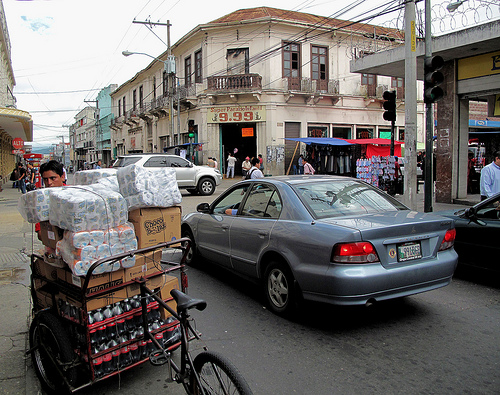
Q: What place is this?
A: It is a city.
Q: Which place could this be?
A: It is a city.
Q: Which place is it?
A: It is a city.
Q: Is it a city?
A: Yes, it is a city.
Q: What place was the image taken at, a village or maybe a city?
A: It was taken at a city.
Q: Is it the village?
A: No, it is the city.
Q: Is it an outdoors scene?
A: Yes, it is outdoors.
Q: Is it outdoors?
A: Yes, it is outdoors.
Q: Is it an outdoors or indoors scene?
A: It is outdoors.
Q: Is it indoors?
A: No, it is outdoors.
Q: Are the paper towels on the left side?
A: Yes, the paper towels are on the left of the image.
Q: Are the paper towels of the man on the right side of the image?
A: No, the paper towels are on the left of the image.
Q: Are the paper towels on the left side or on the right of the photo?
A: The paper towels are on the left of the image.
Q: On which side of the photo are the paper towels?
A: The paper towels are on the left of the image.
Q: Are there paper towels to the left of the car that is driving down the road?
A: Yes, there are paper towels to the left of the car.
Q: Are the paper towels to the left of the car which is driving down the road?
A: Yes, the paper towels are to the left of the car.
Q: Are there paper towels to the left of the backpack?
A: Yes, there are paper towels to the left of the backpack.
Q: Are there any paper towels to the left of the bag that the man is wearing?
A: Yes, there are paper towels to the left of the backpack.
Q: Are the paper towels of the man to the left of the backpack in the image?
A: Yes, the paper towels are to the left of the backpack.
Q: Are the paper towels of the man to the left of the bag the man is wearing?
A: Yes, the paper towels are to the left of the backpack.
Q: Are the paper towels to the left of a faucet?
A: No, the paper towels are to the left of the backpack.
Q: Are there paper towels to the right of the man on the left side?
A: Yes, there are paper towels to the right of the man.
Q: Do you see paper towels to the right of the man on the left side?
A: Yes, there are paper towels to the right of the man.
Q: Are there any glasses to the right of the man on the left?
A: No, there are paper towels to the right of the man.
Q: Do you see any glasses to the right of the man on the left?
A: No, there are paper towels to the right of the man.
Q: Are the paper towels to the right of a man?
A: Yes, the paper towels are to the right of a man.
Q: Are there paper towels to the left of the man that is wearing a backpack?
A: Yes, there are paper towels to the left of the man.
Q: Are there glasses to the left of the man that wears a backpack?
A: No, there are paper towels to the left of the man.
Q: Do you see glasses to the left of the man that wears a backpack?
A: No, there are paper towels to the left of the man.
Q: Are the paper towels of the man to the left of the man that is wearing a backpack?
A: Yes, the paper towels are to the left of the man.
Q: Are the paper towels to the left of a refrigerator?
A: No, the paper towels are to the left of the man.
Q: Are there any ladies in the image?
A: No, there are no ladies.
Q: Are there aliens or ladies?
A: No, there are no ladies or aliens.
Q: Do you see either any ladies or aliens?
A: No, there are no ladies or aliens.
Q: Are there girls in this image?
A: No, there are no girls.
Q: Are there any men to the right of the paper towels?
A: Yes, there is a man to the right of the paper towels.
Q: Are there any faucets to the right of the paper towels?
A: No, there is a man to the right of the paper towels.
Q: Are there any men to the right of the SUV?
A: Yes, there is a man to the right of the SUV.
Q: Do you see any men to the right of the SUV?
A: Yes, there is a man to the right of the SUV.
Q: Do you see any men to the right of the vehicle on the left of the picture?
A: Yes, there is a man to the right of the SUV.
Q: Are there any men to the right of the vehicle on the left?
A: Yes, there is a man to the right of the SUV.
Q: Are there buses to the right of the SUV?
A: No, there is a man to the right of the SUV.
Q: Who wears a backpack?
A: The man wears a backpack.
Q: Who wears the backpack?
A: The man wears a backpack.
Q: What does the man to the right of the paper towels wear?
A: The man wears a backpack.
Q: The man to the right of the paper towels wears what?
A: The man wears a backpack.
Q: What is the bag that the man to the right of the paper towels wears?
A: The bag is a backpack.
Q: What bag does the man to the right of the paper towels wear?
A: The man wears a backpack.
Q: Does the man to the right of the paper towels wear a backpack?
A: Yes, the man wears a backpack.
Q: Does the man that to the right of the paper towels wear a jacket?
A: No, the man wears a backpack.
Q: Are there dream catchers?
A: No, there are no dream catchers.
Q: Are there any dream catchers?
A: No, there are no dream catchers.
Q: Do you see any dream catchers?
A: No, there are no dream catchers.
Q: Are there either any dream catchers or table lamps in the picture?
A: No, there are no dream catchers or table lamps.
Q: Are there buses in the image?
A: No, there are no buses.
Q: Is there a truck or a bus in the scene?
A: No, there are no buses or trucks.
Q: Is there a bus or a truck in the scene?
A: No, there are no buses or trucks.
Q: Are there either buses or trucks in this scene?
A: No, there are no buses or trucks.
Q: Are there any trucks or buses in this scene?
A: No, there are no buses or trucks.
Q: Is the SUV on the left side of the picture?
A: Yes, the SUV is on the left of the image.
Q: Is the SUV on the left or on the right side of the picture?
A: The SUV is on the left of the image.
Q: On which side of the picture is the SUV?
A: The SUV is on the left of the image.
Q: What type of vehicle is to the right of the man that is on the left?
A: The vehicle is a SUV.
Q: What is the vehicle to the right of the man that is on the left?
A: The vehicle is a SUV.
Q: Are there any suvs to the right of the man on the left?
A: Yes, there is a SUV to the right of the man.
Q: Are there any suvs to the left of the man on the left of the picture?
A: No, the SUV is to the right of the man.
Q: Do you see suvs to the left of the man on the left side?
A: No, the SUV is to the right of the man.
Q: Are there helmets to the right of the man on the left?
A: No, there is a SUV to the right of the man.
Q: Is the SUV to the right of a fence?
A: No, the SUV is to the right of a man.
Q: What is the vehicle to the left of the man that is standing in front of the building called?
A: The vehicle is a SUV.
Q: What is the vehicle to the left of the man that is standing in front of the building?
A: The vehicle is a SUV.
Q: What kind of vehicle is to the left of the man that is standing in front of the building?
A: The vehicle is a SUV.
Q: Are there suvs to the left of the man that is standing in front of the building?
A: Yes, there is a SUV to the left of the man.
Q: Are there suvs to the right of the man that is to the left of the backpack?
A: No, the SUV is to the left of the man.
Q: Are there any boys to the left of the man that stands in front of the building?
A: No, there is a SUV to the left of the man.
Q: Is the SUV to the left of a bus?
A: No, the SUV is to the left of the man.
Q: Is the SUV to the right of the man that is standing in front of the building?
A: No, the SUV is to the left of the man.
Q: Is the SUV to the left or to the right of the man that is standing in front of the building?
A: The SUV is to the left of the man.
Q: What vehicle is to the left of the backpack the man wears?
A: The vehicle is a SUV.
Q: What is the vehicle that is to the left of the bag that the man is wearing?
A: The vehicle is a SUV.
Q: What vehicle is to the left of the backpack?
A: The vehicle is a SUV.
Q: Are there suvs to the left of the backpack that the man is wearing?
A: Yes, there is a SUV to the left of the backpack.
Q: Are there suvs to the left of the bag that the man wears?
A: Yes, there is a SUV to the left of the backpack.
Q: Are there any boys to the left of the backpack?
A: No, there is a SUV to the left of the backpack.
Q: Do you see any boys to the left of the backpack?
A: No, there is a SUV to the left of the backpack.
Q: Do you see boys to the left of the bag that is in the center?
A: No, there is a SUV to the left of the backpack.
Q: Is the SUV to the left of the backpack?
A: Yes, the SUV is to the left of the backpack.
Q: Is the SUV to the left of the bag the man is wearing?
A: Yes, the SUV is to the left of the backpack.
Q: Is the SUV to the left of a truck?
A: No, the SUV is to the left of the backpack.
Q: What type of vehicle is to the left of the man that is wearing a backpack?
A: The vehicle is a SUV.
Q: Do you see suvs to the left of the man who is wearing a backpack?
A: Yes, there is a SUV to the left of the man.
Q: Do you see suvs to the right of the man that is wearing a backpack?
A: No, the SUV is to the left of the man.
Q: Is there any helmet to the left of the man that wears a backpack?
A: No, there is a SUV to the left of the man.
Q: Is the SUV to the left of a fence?
A: No, the SUV is to the left of the man.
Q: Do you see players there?
A: No, there are no players.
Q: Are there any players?
A: No, there are no players.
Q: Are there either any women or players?
A: No, there are no players or women.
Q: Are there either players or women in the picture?
A: No, there are no players or women.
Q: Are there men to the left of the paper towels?
A: Yes, there is a man to the left of the paper towels.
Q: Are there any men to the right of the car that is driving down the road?
A: No, the man is to the left of the car.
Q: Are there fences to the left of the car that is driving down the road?
A: No, there is a man to the left of the car.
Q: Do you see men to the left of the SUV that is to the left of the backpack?
A: Yes, there is a man to the left of the SUV.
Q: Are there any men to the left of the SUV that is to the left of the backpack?
A: Yes, there is a man to the left of the SUV.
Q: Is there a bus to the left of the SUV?
A: No, there is a man to the left of the SUV.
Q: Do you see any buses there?
A: No, there are no buses.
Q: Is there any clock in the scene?
A: No, there are no clocks.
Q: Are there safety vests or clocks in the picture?
A: No, there are no clocks or safety vests.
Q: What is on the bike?
A: The seat is on the bike.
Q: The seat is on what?
A: The seat is on the bike.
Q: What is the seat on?
A: The seat is on the bike.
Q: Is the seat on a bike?
A: Yes, the seat is on a bike.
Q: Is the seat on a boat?
A: No, the seat is on a bike.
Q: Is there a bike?
A: Yes, there is a bike.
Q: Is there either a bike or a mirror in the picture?
A: Yes, there is a bike.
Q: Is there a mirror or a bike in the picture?
A: Yes, there is a bike.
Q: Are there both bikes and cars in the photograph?
A: Yes, there are both a bike and a car.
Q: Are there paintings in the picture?
A: No, there are no paintings.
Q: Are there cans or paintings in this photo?
A: No, there are no paintings or cans.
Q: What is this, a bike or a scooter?
A: This is a bike.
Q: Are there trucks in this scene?
A: No, there are no trucks.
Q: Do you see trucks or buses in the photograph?
A: No, there are no trucks or buses.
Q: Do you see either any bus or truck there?
A: No, there are no trucks or buses.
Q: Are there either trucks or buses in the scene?
A: No, there are no trucks or buses.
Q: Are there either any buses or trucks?
A: No, there are no trucks or buses.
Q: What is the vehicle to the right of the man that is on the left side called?
A: The vehicle is a car.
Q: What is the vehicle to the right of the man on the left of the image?
A: The vehicle is a car.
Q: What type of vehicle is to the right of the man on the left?
A: The vehicle is a car.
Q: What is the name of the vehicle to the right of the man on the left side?
A: The vehicle is a car.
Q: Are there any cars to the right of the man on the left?
A: Yes, there is a car to the right of the man.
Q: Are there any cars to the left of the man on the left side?
A: No, the car is to the right of the man.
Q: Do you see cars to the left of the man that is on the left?
A: No, the car is to the right of the man.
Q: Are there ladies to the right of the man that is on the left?
A: No, there is a car to the right of the man.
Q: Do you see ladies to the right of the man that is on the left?
A: No, there is a car to the right of the man.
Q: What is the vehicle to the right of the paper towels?
A: The vehicle is a car.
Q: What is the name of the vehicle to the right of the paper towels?
A: The vehicle is a car.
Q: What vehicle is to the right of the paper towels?
A: The vehicle is a car.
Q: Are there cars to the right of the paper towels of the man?
A: Yes, there is a car to the right of the paper towels.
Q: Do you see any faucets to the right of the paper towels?
A: No, there is a car to the right of the paper towels.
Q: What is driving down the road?
A: The car is driving down the road.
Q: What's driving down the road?
A: The car is driving down the road.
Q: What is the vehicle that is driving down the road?
A: The vehicle is a car.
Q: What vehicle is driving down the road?
A: The vehicle is a car.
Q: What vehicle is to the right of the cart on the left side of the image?
A: The vehicle is a car.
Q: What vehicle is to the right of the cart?
A: The vehicle is a car.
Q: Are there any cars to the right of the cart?
A: Yes, there is a car to the right of the cart.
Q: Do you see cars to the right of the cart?
A: Yes, there is a car to the right of the cart.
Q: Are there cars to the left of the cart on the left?
A: No, the car is to the right of the cart.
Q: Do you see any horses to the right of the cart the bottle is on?
A: No, there is a car to the right of the cart.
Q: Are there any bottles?
A: Yes, there is a bottle.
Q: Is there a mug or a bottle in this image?
A: Yes, there is a bottle.